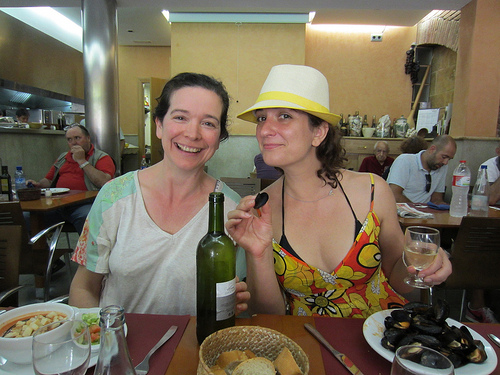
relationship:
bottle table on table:
[195, 190, 236, 348] [4, 298, 498, 373]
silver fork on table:
[131, 322, 178, 374] [74, 312, 499, 373]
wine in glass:
[401, 243, 439, 270] [401, 223, 441, 291]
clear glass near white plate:
[392, 344, 450, 373] [362, 305, 498, 372]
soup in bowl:
[0, 309, 65, 339] [1, 286, 71, 358]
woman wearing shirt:
[68, 68, 248, 320] [72, 170, 244, 317]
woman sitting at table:
[68, 68, 248, 320] [74, 312, 499, 373]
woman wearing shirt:
[68, 68, 248, 320] [71, 185, 222, 312]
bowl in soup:
[3, 300, 75, 365] [3, 308, 68, 340]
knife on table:
[299, 319, 365, 373] [118, 292, 218, 371]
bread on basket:
[191, 322, 296, 370] [195, 323, 315, 373]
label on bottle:
[212, 273, 240, 325] [191, 189, 244, 343]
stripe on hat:
[243, 92, 334, 109] [223, 57, 351, 114]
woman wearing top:
[68, 68, 248, 320] [68, 169, 247, 314]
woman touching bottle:
[68, 68, 248, 320] [191, 189, 244, 343]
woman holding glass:
[227, 62, 451, 320] [401, 223, 441, 291]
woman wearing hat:
[227, 62, 451, 320] [236, 62, 340, 127]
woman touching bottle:
[227, 62, 451, 320] [196, 190, 233, 349]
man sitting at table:
[53, 124, 102, 164] [26, 194, 67, 216]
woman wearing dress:
[247, 72, 397, 316] [265, 187, 403, 319]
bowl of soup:
[0, 301, 74, 371] [8, 301, 95, 333]